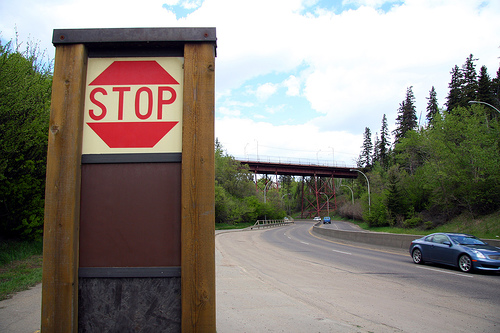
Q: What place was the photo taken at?
A: It was taken at the park.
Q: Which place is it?
A: It is a park.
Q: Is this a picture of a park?
A: Yes, it is showing a park.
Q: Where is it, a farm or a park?
A: It is a park.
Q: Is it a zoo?
A: No, it is a park.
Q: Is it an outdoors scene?
A: Yes, it is outdoors.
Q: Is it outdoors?
A: Yes, it is outdoors.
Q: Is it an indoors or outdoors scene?
A: It is outdoors.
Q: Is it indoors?
A: No, it is outdoors.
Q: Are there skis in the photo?
A: No, there are no skis.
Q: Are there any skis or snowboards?
A: No, there are no skis or snowboards.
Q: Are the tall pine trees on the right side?
A: Yes, the pine trees are on the right of the image.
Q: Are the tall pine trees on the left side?
A: No, the pines are on the right of the image.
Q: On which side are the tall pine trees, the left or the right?
A: The pine trees are on the right of the image.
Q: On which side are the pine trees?
A: The pine trees are on the right of the image.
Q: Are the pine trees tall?
A: Yes, the pine trees are tall.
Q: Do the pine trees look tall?
A: Yes, the pine trees are tall.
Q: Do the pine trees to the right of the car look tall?
A: Yes, the pine trees are tall.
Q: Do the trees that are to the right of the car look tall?
A: Yes, the pine trees are tall.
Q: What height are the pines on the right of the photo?
A: The pines are tall.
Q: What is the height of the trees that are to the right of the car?
A: The pines are tall.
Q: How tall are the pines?
A: The pines are tall.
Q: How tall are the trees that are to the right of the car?
A: The pines are tall.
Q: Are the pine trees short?
A: No, the pine trees are tall.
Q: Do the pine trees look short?
A: No, the pine trees are tall.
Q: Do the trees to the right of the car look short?
A: No, the pine trees are tall.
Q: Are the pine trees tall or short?
A: The pine trees are tall.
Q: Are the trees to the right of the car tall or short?
A: The pine trees are tall.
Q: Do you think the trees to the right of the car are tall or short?
A: The pine trees are tall.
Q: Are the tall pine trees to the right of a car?
A: Yes, the pines are to the right of a car.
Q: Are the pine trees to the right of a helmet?
A: No, the pine trees are to the right of a car.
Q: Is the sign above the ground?
A: Yes, the sign is above the ground.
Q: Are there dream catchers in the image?
A: No, there are no dream catchers.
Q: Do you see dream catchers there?
A: No, there are no dream catchers.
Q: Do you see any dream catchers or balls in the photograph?
A: No, there are no dream catchers or balls.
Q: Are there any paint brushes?
A: No, there are no paint brushes.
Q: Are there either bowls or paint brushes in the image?
A: No, there are no paint brushes or bowls.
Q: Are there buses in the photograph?
A: No, there are no buses.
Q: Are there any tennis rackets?
A: No, there are no tennis rackets.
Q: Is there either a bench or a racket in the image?
A: No, there are no rackets or benches.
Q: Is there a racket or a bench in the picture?
A: No, there are no rackets or benches.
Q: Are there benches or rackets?
A: No, there are no rackets or benches.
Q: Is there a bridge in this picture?
A: Yes, there is a bridge.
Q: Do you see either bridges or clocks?
A: Yes, there is a bridge.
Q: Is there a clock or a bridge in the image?
A: Yes, there is a bridge.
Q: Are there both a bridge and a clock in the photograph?
A: No, there is a bridge but no clocks.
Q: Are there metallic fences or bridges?
A: Yes, there is a metal bridge.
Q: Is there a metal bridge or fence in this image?
A: Yes, there is a metal bridge.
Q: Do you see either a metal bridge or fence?
A: Yes, there is a metal bridge.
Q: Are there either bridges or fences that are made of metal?
A: Yes, the bridge is made of metal.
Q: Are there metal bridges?
A: Yes, there is a metal bridge.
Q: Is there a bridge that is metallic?
A: Yes, there is a bridge that is metallic.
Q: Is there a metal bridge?
A: Yes, there is a bridge that is made of metal.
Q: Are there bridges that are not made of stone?
A: Yes, there is a bridge that is made of metal.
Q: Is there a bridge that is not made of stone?
A: Yes, there is a bridge that is made of metal.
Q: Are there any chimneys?
A: No, there are no chimneys.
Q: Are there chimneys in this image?
A: No, there are no chimneys.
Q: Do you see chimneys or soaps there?
A: No, there are no chimneys or soaps.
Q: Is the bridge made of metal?
A: Yes, the bridge is made of metal.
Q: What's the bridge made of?
A: The bridge is made of metal.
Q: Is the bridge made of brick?
A: No, the bridge is made of metal.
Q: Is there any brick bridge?
A: No, there is a bridge but it is made of metal.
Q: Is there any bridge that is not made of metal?
A: No, there is a bridge but it is made of metal.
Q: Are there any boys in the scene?
A: No, there are no boys.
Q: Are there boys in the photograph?
A: No, there are no boys.